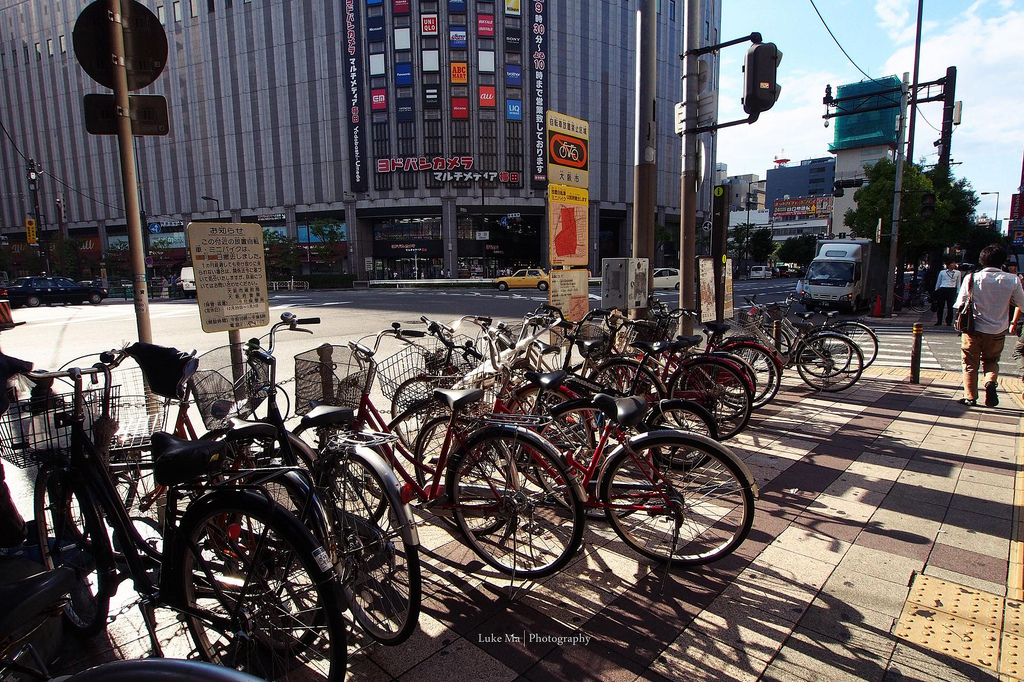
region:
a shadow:
[815, 492, 920, 554]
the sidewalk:
[914, 487, 990, 536]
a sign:
[183, 225, 282, 339]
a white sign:
[186, 215, 281, 330]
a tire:
[293, 544, 358, 609]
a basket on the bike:
[0, 400, 62, 452]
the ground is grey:
[317, 294, 393, 336]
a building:
[235, 70, 305, 141]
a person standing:
[951, 236, 1013, 392]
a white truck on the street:
[806, 234, 864, 310]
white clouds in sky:
[945, 4, 991, 97]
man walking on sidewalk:
[945, 195, 1021, 423]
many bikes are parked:
[28, 315, 826, 670]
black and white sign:
[176, 212, 304, 348]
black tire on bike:
[597, 443, 752, 589]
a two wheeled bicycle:
[9, 354, 332, 665]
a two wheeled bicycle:
[284, 310, 583, 595]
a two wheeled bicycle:
[472, 319, 748, 555]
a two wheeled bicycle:
[521, 292, 684, 460]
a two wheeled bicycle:
[634, 278, 813, 509]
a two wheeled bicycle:
[730, 297, 857, 433]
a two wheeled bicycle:
[771, 307, 895, 361]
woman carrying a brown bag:
[949, 241, 1022, 404]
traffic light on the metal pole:
[671, 3, 788, 305]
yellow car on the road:
[482, 263, 547, 298]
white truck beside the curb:
[795, 233, 872, 314]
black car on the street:
[2, 271, 113, 306]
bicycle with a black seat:
[4, 344, 353, 680]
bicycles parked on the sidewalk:
[1, 300, 883, 677]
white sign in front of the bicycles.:
[177, 214, 272, 373]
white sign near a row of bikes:
[182, 209, 277, 340]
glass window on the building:
[314, 178, 324, 205]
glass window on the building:
[310, 118, 320, 157]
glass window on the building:
[304, 77, 318, 119]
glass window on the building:
[305, 27, 312, 81]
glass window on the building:
[275, 163, 282, 209]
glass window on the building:
[269, 125, 283, 164]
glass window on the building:
[266, 80, 276, 129]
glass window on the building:
[238, 169, 248, 208]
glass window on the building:
[231, 131, 245, 173]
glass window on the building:
[229, 91, 245, 131]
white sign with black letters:
[186, 216, 275, 340]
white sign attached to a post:
[186, 219, 269, 387]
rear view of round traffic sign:
[72, 2, 172, 92]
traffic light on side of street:
[742, 34, 785, 118]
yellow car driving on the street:
[493, 262, 552, 295]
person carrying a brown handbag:
[949, 240, 1022, 412]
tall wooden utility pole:
[632, 2, 662, 296]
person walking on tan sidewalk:
[951, 240, 1019, 406]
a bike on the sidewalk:
[488, 426, 730, 560]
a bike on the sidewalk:
[184, 472, 353, 679]